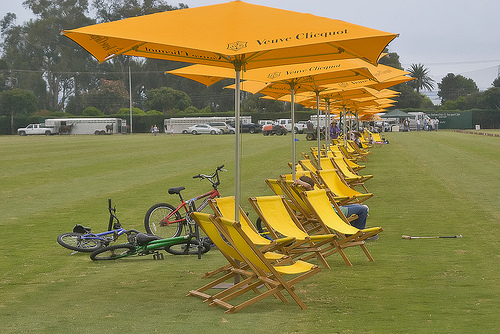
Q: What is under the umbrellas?
A: Chairs.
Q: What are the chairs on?
A: Grass.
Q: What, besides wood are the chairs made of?
A: Fabric.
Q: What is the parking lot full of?
A: Vehicles.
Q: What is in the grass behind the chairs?
A: Bikes.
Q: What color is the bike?
A: Red.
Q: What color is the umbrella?
A: Yellow.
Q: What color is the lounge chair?
A: Yellow.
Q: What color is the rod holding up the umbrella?
A: Silver.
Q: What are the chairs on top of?
A: Grass.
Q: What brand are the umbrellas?
A: Veuve Chequot.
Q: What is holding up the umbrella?
A: A silver rod.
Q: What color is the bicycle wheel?
A: Black.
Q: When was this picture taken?
A: Daytime.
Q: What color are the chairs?
A: Yellow.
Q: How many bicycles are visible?
A: 3.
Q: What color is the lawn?
A: Green.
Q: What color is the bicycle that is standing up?
A: Red.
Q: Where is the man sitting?
A: Lawn chair.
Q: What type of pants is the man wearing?
A: Jeans.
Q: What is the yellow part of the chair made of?
A: Fabric.